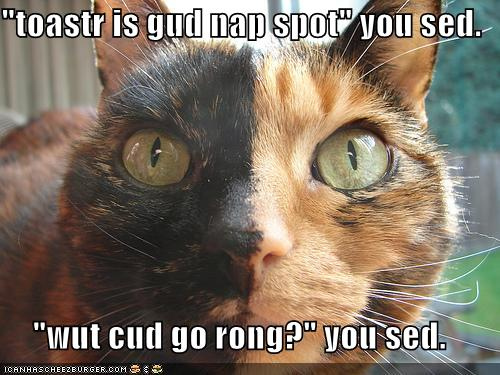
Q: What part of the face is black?
A: Left side.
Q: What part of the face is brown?
A: Right side.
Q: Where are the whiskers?
A: Below the eyes.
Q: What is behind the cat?
A: Fence.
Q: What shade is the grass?
A: Green.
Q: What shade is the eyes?
A: Green.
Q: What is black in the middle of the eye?
A: Pupil.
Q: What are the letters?
A: White.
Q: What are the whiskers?
A: White.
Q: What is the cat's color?
A: Orange.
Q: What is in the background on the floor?
A: Grass.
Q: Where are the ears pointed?
A: Upward.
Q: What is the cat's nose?
A: Black and orange.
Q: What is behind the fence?
A: Trees.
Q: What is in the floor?
A: Trees.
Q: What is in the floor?
A: Cat.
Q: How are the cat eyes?
A: Big.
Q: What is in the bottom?
A: Text.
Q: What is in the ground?
A: Cat.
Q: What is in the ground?
A: Cat.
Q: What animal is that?
A: A cat.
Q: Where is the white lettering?
A: Top and bottom.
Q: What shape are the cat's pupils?
A: Oval.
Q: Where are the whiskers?
A: On the cat's face.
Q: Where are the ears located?
A: On the cat's head.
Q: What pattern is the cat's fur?
A: Stripes.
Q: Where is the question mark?
A: Bottom line.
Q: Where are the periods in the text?
A: After the word SED.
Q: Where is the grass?
A: Behind the cat.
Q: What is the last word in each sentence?
A: Sed.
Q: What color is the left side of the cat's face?
A: Black.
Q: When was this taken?
A: Daytime.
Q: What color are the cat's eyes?
A: Green.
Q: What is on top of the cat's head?
A: Ears.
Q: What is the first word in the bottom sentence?
A: Wut.